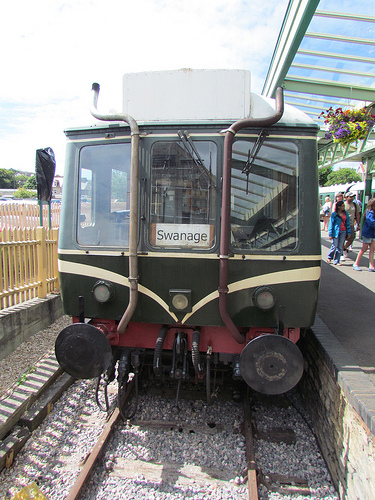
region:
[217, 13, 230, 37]
There are very, very bright white clouds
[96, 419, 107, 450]
There are railroad tracks that are very brown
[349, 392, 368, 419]
There are dark black sides on this track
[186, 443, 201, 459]
There are pea gravel that are on the track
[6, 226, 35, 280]
There is a light brown fence to the left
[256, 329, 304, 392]
There is a black stopper on the front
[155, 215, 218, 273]
This sign says "Swanage" on it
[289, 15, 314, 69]
There is a green and white awning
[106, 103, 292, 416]
Jackson Zander took this photo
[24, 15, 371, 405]
Train at the station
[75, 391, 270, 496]
Railway tracks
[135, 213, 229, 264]
Swanage sign on the train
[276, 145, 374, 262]
Passengers stepped out of the train compartment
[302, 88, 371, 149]
Flowers on the railway station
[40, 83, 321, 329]
Green train engine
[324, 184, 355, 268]
A woman in blue jacket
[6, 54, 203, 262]
Sunny day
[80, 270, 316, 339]
Engine head lights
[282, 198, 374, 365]
Shadow of the train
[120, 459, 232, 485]
small piece of wood on track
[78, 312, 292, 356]
red color at bottom of train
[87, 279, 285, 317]
small white lights on train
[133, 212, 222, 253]
white and brown sign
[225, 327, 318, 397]
large black white disc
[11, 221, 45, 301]
large brown fence at the side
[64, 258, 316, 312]
white lines on the front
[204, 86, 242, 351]
red pipe on the grass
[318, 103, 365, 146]
colorful flowers on the roof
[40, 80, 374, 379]
blue and black train on track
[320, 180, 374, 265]
people walking on platform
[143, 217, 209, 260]
sign says swanage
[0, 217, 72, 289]
fence made of wood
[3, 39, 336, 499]
train on tracks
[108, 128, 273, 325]
pipes are 2 shades of brown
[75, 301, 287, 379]
bottom of train is red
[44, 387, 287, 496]
rocks between train tracks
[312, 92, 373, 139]
flowers on structure of ceiling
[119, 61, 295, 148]
top of train is white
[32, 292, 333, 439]
2 circular objects on front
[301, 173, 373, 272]
several people standing on a train plate form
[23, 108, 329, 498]
a green and white train car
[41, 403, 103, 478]
gravel next to the train tracks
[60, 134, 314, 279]
windows on a train car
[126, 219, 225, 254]
a sign in the window of a train car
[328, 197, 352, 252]
a woman wearing a blue jacket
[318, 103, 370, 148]
a hanging flower basket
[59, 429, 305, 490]
set of train tracks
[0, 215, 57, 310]
a wooden fence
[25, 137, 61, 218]
a black plastic bag covering a sign